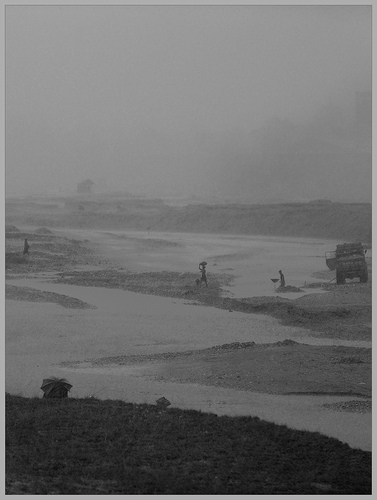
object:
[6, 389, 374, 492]
hill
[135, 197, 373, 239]
hill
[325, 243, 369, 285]
jeep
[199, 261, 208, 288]
person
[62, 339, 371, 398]
land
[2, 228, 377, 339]
land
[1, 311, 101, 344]
water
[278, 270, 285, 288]
human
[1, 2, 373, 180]
cloud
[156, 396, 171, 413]
cow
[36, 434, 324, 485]
grass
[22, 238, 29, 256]
person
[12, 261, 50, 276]
sand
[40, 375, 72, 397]
persons